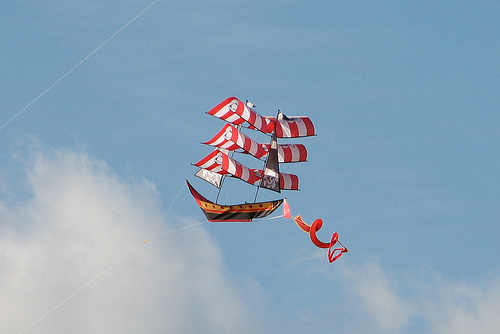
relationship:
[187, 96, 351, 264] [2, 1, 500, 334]
kite in sky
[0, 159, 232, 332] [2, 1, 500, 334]
cloud in sky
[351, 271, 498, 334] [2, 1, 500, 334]
cloud in sky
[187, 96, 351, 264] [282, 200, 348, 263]
kite has a tail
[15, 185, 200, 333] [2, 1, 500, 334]
string in sky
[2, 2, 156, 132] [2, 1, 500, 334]
string in sky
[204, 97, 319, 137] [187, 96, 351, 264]
top of kite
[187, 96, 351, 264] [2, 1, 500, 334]
kite flying in sky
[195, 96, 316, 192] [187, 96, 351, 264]
sails are on kite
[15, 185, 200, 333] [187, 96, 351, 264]
string attached to kite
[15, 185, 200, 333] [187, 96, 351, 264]
string holding kite